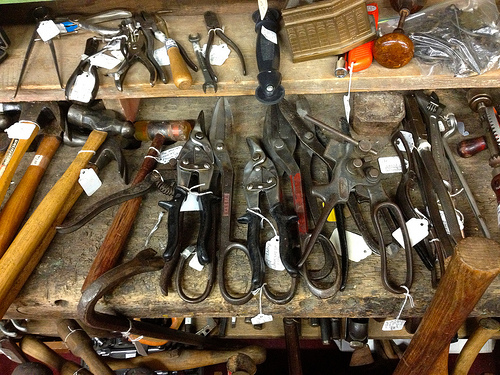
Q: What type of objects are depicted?
A: Tools.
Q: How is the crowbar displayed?
A: Hanging from the middle shelf.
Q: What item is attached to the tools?
A: A small, white tag.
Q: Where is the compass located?
A: On the left hand side of the top shelf.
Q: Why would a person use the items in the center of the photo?
A: To cut things.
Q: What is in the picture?
A: An assortment of tools.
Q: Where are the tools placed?
A: On shelves.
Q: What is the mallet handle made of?
A: Wood.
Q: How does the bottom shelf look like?
A: Grey.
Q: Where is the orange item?
A: On the top shelf.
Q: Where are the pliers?
A: On the second shelf.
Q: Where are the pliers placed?
A: On the right half of the second shelf.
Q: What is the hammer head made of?
A: Metal.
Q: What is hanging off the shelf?
A: A pry bar.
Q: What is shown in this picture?
A: Various tools spread out.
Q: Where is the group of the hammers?
A: On the left.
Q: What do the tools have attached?
A: White tags.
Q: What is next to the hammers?
A: A pair of pliers.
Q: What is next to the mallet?
A: A hammer.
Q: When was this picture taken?
A: Afternoon.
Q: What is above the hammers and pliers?
A: A shelf full of tools.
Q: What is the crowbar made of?
A: Iron/Steel.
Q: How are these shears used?
A: By hand.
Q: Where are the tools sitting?
A: On a shelf.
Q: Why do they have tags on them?
A: They are for sale.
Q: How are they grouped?
A: By like items.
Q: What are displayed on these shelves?
A: Tools.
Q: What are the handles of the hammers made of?
A: Wood.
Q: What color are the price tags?
A: White.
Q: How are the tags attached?
A: With string.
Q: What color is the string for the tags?
A: White.